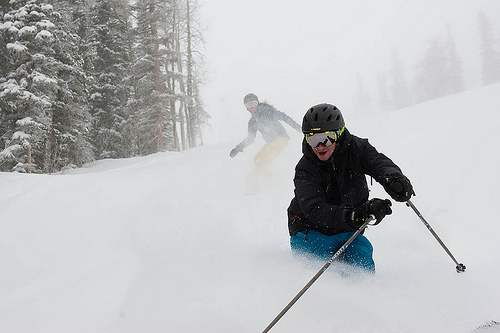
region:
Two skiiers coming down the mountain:
[232, 78, 454, 298]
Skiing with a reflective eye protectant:
[297, 97, 349, 164]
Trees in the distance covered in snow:
[352, 27, 454, 110]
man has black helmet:
[275, 100, 409, 162]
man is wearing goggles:
[301, 127, 336, 153]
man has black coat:
[297, 141, 366, 233]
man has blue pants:
[261, 212, 382, 292]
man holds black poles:
[261, 189, 440, 329]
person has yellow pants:
[243, 134, 286, 186]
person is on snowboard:
[225, 96, 289, 205]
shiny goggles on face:
[288, 123, 365, 150]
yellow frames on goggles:
[328, 118, 365, 143]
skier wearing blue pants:
[282, 220, 412, 274]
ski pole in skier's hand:
[325, 191, 407, 241]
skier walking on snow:
[222, 86, 294, 178]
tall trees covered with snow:
[12, 48, 77, 173]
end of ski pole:
[446, 260, 475, 275]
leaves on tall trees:
[74, 47, 151, 121]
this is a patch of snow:
[133, 264, 160, 293]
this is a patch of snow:
[347, 311, 420, 323]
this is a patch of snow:
[36, 180, 119, 274]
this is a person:
[298, 107, 383, 262]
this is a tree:
[179, 5, 201, 142]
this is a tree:
[144, 0, 174, 140]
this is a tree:
[6, 21, 56, 157]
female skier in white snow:
[274, 99, 394, 279]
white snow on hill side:
[111, 235, 138, 257]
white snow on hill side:
[171, 258, 196, 283]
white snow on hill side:
[77, 253, 115, 295]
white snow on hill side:
[387, 271, 419, 303]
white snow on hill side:
[442, 156, 464, 191]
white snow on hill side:
[150, 208, 192, 259]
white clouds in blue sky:
[341, 25, 373, 76]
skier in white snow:
[291, 93, 389, 300]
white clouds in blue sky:
[294, 22, 316, 47]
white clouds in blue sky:
[388, 18, 430, 45]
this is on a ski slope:
[55, 20, 408, 283]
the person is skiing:
[265, 99, 384, 241]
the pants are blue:
[299, 210, 426, 304]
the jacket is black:
[309, 167, 489, 262]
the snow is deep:
[34, 125, 241, 301]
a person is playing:
[298, 92, 413, 293]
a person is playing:
[223, 79, 308, 191]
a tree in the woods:
[462, 11, 496, 80]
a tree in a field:
[436, 23, 473, 108]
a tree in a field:
[415, 36, 450, 104]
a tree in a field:
[375, 39, 410, 110]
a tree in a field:
[170, 0, 220, 145]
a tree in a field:
[7, 3, 92, 177]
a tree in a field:
[72, 5, 150, 162]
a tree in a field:
[335, 69, 377, 120]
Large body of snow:
[70, 195, 209, 296]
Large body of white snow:
[111, 207, 232, 310]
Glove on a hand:
[353, 193, 393, 228]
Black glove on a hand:
[350, 195, 399, 232]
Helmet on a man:
[297, 102, 348, 165]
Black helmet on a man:
[295, 100, 345, 140]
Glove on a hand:
[384, 168, 417, 205]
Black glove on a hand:
[384, 171, 419, 209]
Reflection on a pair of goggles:
[303, 132, 338, 147]